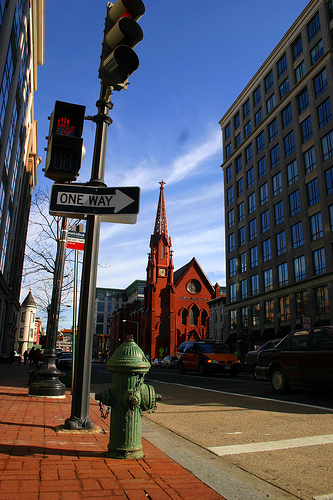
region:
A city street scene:
[7, 8, 321, 494]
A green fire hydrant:
[95, 329, 159, 469]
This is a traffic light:
[94, 0, 149, 135]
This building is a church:
[142, 176, 220, 362]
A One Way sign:
[44, 178, 149, 226]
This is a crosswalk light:
[39, 94, 101, 183]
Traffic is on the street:
[173, 321, 331, 390]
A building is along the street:
[219, 81, 331, 349]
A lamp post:
[28, 223, 64, 396]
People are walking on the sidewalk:
[4, 342, 43, 369]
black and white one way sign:
[50, 184, 143, 213]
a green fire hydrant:
[94, 333, 162, 459]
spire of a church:
[147, 177, 169, 356]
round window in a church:
[184, 279, 201, 296]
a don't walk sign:
[49, 102, 87, 141]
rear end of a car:
[254, 324, 332, 388]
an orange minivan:
[177, 339, 241, 375]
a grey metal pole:
[65, 90, 114, 432]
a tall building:
[228, 0, 331, 342]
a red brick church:
[110, 180, 217, 363]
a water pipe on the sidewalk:
[70, 312, 176, 498]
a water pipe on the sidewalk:
[86, 330, 143, 468]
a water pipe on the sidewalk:
[86, 391, 143, 486]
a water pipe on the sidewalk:
[68, 311, 143, 395]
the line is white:
[238, 444, 239, 458]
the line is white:
[230, 437, 238, 454]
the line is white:
[246, 445, 253, 455]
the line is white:
[248, 447, 254, 451]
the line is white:
[239, 447, 247, 455]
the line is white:
[223, 447, 231, 458]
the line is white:
[217, 448, 221, 454]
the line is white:
[217, 445, 222, 460]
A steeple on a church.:
[142, 163, 175, 251]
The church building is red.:
[102, 169, 223, 352]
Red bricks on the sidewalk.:
[5, 399, 73, 487]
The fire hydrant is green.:
[94, 331, 165, 464]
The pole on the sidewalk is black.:
[57, 220, 103, 434]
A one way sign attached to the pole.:
[40, 174, 150, 236]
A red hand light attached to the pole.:
[41, 87, 90, 139]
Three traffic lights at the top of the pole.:
[78, 1, 161, 96]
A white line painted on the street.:
[204, 409, 329, 459]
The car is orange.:
[164, 320, 241, 379]